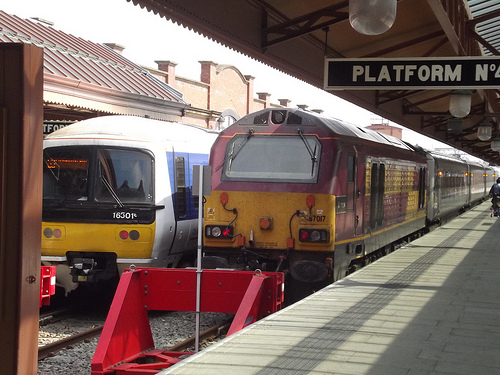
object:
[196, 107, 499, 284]
train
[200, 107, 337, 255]
end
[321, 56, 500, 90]
sign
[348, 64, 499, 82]
platform number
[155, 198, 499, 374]
walkway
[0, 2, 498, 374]
train station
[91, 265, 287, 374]
blockade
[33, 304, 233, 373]
track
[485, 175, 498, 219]
person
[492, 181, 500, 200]
back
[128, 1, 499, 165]
roof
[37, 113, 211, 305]
train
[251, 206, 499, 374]
shadow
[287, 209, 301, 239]
cord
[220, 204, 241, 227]
cord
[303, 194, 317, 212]
light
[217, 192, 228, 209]
light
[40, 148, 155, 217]
windshield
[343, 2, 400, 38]
light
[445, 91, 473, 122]
light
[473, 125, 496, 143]
light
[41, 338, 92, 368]
gravel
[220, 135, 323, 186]
window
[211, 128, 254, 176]
windshield wiper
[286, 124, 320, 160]
windshield wiper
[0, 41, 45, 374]
bearn